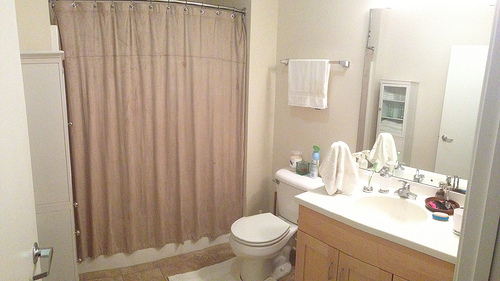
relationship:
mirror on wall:
[354, 6, 491, 184] [269, 1, 496, 222]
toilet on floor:
[220, 155, 322, 280] [66, 203, 352, 280]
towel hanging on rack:
[286, 58, 332, 111] [280, 55, 352, 71]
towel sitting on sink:
[320, 141, 360, 198] [292, 161, 473, 279]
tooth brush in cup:
[383, 159, 393, 177] [374, 168, 395, 197]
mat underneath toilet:
[167, 244, 297, 279] [220, 155, 322, 280]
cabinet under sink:
[289, 208, 456, 280] [292, 161, 473, 279]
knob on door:
[438, 132, 454, 148] [432, 40, 489, 178]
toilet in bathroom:
[220, 155, 322, 280] [2, 2, 500, 280]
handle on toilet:
[269, 177, 284, 187] [220, 155, 322, 280]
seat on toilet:
[227, 211, 287, 245] [220, 155, 322, 280]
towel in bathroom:
[286, 58, 332, 111] [2, 2, 500, 280]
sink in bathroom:
[292, 161, 473, 279] [2, 2, 500, 280]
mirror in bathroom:
[354, 6, 491, 184] [2, 2, 500, 280]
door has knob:
[432, 40, 489, 178] [438, 132, 454, 148]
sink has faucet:
[292, 161, 473, 279] [391, 176, 419, 203]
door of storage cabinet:
[433, 40, 489, 179] [371, 74, 419, 169]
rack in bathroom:
[280, 55, 352, 71] [2, 2, 500, 280]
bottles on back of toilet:
[283, 142, 324, 180] [220, 155, 322, 280]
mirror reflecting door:
[354, 6, 491, 184] [432, 40, 489, 178]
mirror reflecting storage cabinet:
[354, 6, 491, 184] [371, 74, 419, 169]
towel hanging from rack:
[286, 58, 332, 111] [280, 55, 352, 71]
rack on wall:
[280, 55, 352, 71] [269, 1, 496, 222]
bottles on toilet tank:
[283, 142, 324, 180] [271, 167, 320, 222]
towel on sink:
[320, 141, 360, 198] [292, 161, 473, 279]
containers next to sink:
[425, 183, 469, 241] [292, 161, 473, 279]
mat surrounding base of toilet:
[167, 244, 297, 279] [220, 155, 322, 280]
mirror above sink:
[354, 6, 491, 184] [292, 161, 473, 279]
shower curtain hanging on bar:
[50, 1, 249, 262] [160, 1, 253, 14]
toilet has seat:
[220, 155, 322, 280] [227, 211, 287, 245]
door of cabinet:
[433, 40, 489, 179] [289, 208, 456, 280]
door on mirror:
[433, 40, 489, 179] [354, 6, 491, 184]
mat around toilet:
[167, 244, 297, 279] [220, 155, 322, 280]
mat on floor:
[167, 244, 297, 279] [66, 203, 352, 280]